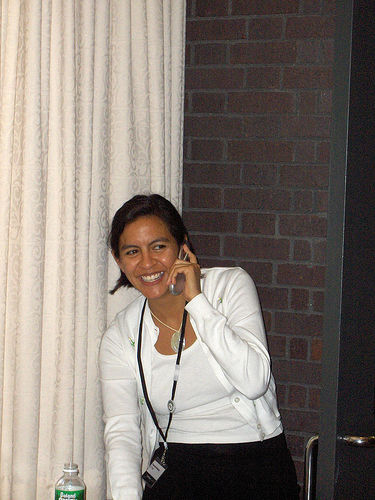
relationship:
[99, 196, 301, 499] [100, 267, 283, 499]
girl wearing cardigan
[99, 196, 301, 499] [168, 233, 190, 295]
girl on phone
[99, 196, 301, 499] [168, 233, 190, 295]
girl holding phone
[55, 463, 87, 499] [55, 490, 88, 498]
water bottle has label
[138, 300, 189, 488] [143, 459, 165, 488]
lanyard has name tag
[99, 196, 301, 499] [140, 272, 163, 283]
girl has teeth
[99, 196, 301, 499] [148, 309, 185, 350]
girl wearing necklace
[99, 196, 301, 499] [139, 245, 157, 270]
girl has nose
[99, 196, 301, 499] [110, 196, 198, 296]
girl has hair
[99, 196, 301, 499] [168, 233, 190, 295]
girl talking on phone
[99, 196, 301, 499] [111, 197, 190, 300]
girl has head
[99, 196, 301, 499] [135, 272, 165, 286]
girl has smile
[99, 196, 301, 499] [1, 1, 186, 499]
girl in front of curtain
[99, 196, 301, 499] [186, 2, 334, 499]
girl in front of brick wall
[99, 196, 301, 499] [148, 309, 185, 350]
girl has necklace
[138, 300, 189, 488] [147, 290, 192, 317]
lanyard around neck